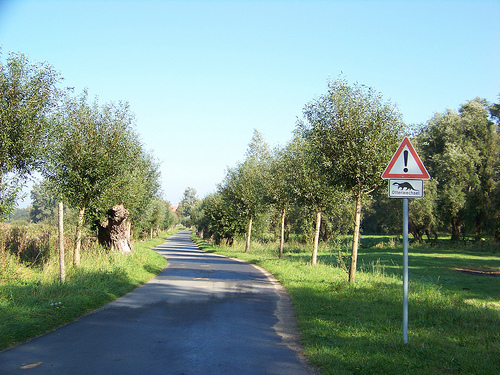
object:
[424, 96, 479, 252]
trees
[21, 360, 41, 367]
yellow spot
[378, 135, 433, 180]
street sign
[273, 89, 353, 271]
trees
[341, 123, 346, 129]
leaves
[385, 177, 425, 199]
sign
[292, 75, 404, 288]
trees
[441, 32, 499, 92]
clouds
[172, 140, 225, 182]
white clouds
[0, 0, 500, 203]
sky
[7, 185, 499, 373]
area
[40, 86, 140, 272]
tree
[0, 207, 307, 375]
road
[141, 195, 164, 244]
trees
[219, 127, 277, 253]
trees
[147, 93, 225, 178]
white clouds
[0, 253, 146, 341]
tall grass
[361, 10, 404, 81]
clouds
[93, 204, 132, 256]
tree stump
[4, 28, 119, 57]
clouds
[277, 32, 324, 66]
clouds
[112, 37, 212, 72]
clouds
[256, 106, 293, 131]
clouds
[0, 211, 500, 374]
ground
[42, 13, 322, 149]
sun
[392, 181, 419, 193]
brontosaurus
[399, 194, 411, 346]
pole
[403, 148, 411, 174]
exclamation mark